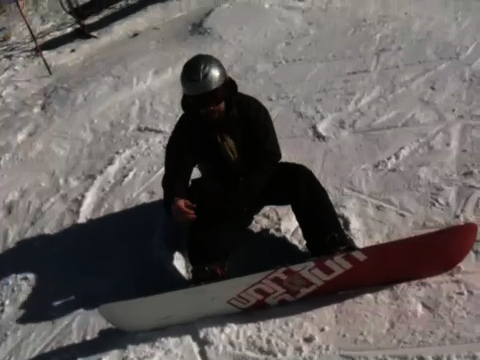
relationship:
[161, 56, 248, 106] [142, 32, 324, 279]
helmet on man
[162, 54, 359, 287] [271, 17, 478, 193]
man sitting in snow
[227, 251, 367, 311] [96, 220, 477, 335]
logo on snowboard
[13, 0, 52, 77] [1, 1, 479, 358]
pole on ground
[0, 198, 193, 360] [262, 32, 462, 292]
shadow on snow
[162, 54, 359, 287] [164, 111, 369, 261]
man on snow suit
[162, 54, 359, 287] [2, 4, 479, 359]
man on snow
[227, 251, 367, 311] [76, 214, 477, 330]
logo on snowboard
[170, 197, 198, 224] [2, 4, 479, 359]
hand in snow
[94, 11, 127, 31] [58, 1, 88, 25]
shadow in stick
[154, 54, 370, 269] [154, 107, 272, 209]
man in coat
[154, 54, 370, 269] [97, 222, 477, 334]
man in snowboard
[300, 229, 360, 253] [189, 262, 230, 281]
boot in foot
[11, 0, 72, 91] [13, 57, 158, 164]
pole in snow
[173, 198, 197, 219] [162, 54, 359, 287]
hand of man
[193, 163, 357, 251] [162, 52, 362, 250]
legs of person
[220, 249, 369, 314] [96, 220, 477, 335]
logo of snowboard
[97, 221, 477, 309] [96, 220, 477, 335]
side of snowboard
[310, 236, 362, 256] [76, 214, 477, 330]
foot on snowboard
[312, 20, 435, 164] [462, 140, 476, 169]
snow on ground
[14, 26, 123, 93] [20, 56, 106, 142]
stick in snow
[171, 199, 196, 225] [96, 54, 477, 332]
hand in snow suit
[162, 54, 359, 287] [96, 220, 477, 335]
man with snowboard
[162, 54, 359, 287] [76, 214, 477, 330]
man with snowboard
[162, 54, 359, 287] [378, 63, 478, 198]
man sitting in snow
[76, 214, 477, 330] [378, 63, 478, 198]
snowboard sitting in snow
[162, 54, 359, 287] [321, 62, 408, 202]
man sitting in snow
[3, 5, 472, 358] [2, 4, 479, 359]
tracks in snow